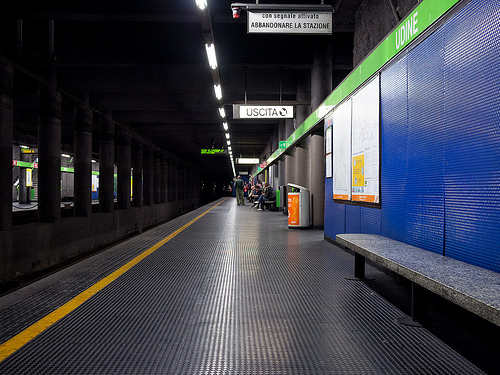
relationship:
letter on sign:
[251, 22, 330, 29] [247, 6, 336, 36]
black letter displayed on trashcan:
[247, 108, 287, 116] [282, 180, 314, 229]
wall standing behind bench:
[399, 80, 459, 157] [298, 201, 498, 343]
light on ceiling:
[215, 83, 222, 101] [162, 8, 251, 170]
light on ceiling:
[205, 43, 218, 69] [162, 8, 251, 170]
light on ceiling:
[193, 2, 210, 8] [162, 8, 251, 170]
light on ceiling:
[219, 108, 227, 119] [162, 8, 251, 170]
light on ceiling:
[224, 133, 231, 138] [162, 8, 251, 170]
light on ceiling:
[226, 145, 231, 150] [162, 8, 251, 170]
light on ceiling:
[219, 108, 227, 119] [165, 3, 425, 153]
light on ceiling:
[222, 121, 229, 131] [37, 2, 285, 181]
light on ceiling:
[225, 133, 230, 139] [37, 2, 285, 181]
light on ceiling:
[216, 106, 227, 117] [37, 2, 285, 181]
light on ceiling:
[214, 84, 223, 100] [37, 2, 285, 181]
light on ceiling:
[205, 43, 218, 69] [37, 2, 285, 181]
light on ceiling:
[205, 43, 218, 69] [143, 3, 418, 178]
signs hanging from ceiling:
[229, 10, 334, 123] [24, 1, 412, 195]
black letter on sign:
[247, 108, 287, 116] [216, 83, 320, 137]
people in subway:
[233, 171, 274, 206] [0, 2, 468, 342]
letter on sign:
[260, 20, 266, 28] [245, 7, 333, 37]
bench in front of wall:
[334, 223, 498, 347] [314, 2, 488, 282]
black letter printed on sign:
[245, 106, 253, 118] [235, 102, 294, 119]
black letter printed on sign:
[247, 108, 287, 116] [229, 102, 297, 118]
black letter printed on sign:
[247, 108, 287, 116] [239, 105, 294, 119]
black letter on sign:
[247, 108, 287, 116] [228, 95, 296, 125]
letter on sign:
[251, 22, 330, 29] [239, 102, 334, 121]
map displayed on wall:
[332, 70, 382, 209] [324, 105, 496, 155]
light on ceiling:
[199, 37, 223, 77] [82, 14, 172, 89]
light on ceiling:
[223, 122, 229, 131] [13, 2, 350, 147]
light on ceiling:
[214, 84, 223, 100] [223, 22, 322, 137]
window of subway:
[47, 145, 87, 219] [0, 60, 204, 289]